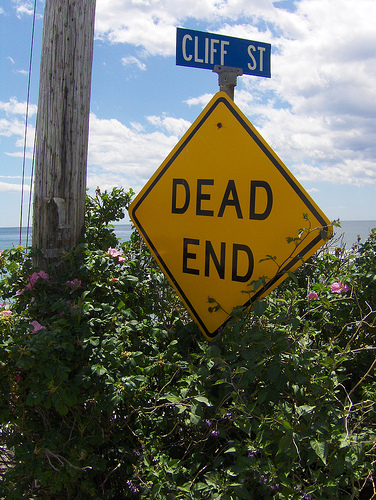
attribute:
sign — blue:
[170, 20, 274, 80]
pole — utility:
[35, 1, 102, 250]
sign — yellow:
[107, 91, 349, 333]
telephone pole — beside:
[128, 90, 337, 342]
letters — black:
[169, 175, 275, 220]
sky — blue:
[90, 24, 180, 155]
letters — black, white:
[171, 179, 272, 279]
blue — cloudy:
[0, 2, 373, 229]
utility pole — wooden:
[27, 1, 96, 267]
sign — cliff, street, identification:
[172, 29, 278, 90]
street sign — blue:
[174, 26, 271, 78]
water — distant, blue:
[0, 220, 373, 249]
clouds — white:
[284, 8, 374, 164]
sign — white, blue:
[173, 27, 273, 80]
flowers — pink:
[301, 277, 349, 301]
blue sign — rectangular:
[175, 27, 271, 76]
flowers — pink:
[27, 318, 44, 332]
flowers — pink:
[105, 246, 120, 256]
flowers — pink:
[304, 289, 317, 300]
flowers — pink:
[328, 280, 348, 293]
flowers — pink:
[37, 270, 48, 280]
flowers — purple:
[293, 483, 310, 499]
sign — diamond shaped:
[139, 152, 307, 323]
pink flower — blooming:
[327, 279, 349, 301]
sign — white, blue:
[171, 20, 284, 85]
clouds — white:
[303, 15, 374, 141]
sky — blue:
[96, 0, 374, 226]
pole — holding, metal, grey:
[212, 62, 243, 103]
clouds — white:
[275, 4, 375, 125]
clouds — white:
[259, 110, 374, 179]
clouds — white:
[96, 0, 174, 52]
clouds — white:
[88, 112, 175, 168]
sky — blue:
[2, 1, 364, 216]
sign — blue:
[175, 19, 274, 87]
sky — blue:
[111, 15, 346, 163]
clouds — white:
[273, 12, 349, 145]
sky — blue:
[102, 31, 188, 129]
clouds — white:
[294, 23, 348, 137]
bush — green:
[132, 303, 322, 463]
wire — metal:
[16, 29, 42, 182]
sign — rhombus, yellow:
[118, 90, 338, 347]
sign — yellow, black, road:
[132, 90, 328, 344]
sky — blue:
[101, 16, 160, 150]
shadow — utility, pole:
[21, 258, 138, 493]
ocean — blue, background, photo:
[334, 213, 373, 253]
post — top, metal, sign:
[212, 66, 238, 104]